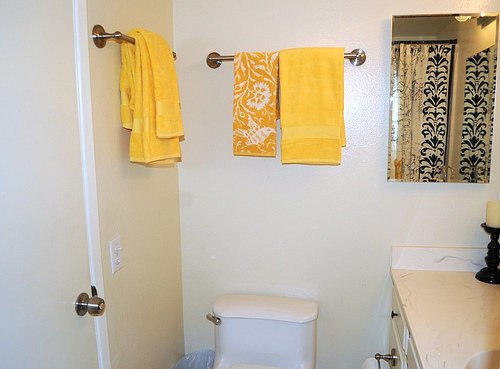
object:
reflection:
[386, 16, 496, 182]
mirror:
[386, 11, 499, 183]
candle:
[486, 201, 499, 229]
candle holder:
[475, 223, 499, 285]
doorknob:
[75, 292, 106, 316]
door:
[0, 0, 107, 369]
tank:
[206, 294, 319, 367]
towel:
[233, 51, 281, 157]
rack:
[92, 24, 177, 58]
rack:
[206, 49, 367, 70]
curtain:
[391, 41, 456, 183]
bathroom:
[5, 2, 499, 367]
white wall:
[0, 0, 97, 312]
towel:
[278, 46, 347, 166]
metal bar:
[206, 49, 366, 69]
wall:
[170, 0, 499, 354]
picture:
[13, 14, 499, 367]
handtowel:
[119, 27, 185, 164]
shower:
[389, 18, 498, 198]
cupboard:
[387, 39, 458, 182]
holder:
[472, 223, 499, 283]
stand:
[475, 223, 499, 286]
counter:
[386, 268, 499, 368]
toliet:
[207, 295, 319, 367]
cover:
[213, 287, 320, 324]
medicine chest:
[384, 12, 498, 187]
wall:
[77, 3, 185, 369]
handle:
[374, 348, 396, 367]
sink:
[392, 238, 485, 364]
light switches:
[109, 236, 123, 275]